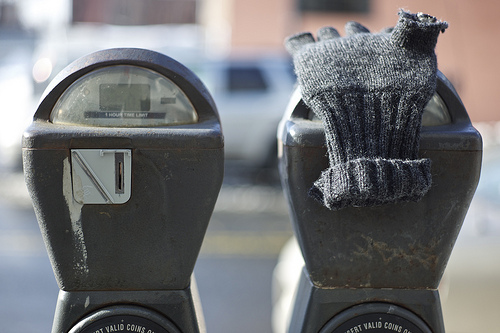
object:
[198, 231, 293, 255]
line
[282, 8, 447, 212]
glove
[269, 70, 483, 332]
meter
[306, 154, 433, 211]
bottom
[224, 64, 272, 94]
window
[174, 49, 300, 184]
car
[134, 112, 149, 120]
words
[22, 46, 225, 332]
meter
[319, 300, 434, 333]
dial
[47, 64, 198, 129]
dial